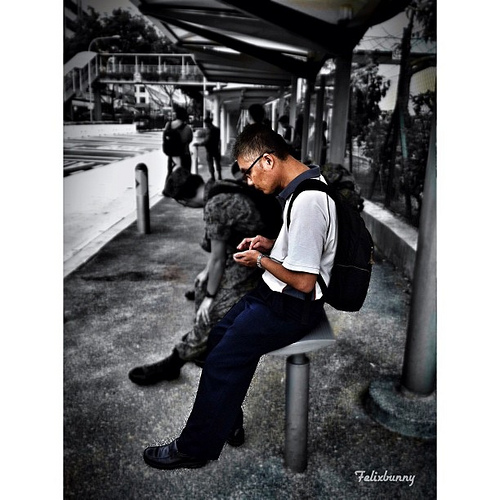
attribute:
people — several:
[153, 92, 362, 381]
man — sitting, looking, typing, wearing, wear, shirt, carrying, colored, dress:
[157, 83, 423, 433]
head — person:
[224, 107, 309, 209]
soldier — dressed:
[129, 173, 293, 381]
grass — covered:
[44, 257, 167, 386]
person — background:
[139, 61, 381, 390]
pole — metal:
[246, 349, 347, 491]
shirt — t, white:
[249, 199, 376, 287]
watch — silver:
[248, 234, 281, 278]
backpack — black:
[288, 155, 438, 335]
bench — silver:
[204, 297, 357, 404]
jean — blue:
[165, 285, 296, 413]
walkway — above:
[84, 144, 180, 238]